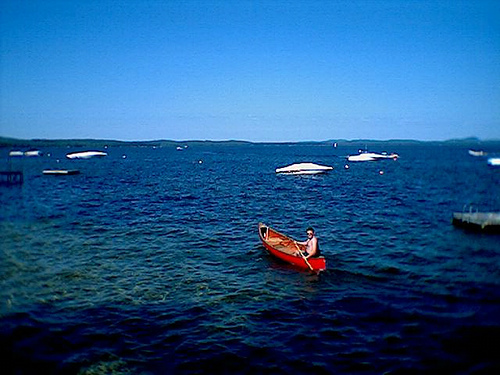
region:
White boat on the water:
[276, 158, 336, 177]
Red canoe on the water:
[255, 222, 328, 274]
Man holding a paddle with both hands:
[293, 240, 319, 282]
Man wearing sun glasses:
[306, 231, 314, 235]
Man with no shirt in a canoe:
[293, 227, 321, 259]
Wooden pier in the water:
[450, 205, 499, 230]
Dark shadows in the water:
[2, 298, 499, 369]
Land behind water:
[0, 133, 498, 145]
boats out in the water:
[2, 145, 499, 373]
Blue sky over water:
[1, 1, 498, 136]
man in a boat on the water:
[255, 216, 330, 279]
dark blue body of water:
[0, 146, 497, 373]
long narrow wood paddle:
[291, 239, 321, 276]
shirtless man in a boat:
[293, 227, 319, 254]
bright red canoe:
[257, 220, 325, 277]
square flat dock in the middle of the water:
[38, 166, 81, 177]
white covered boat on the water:
[271, 158, 336, 179]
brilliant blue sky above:
[0, 0, 499, 142]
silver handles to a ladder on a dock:
[462, 200, 480, 217]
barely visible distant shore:
[0, 134, 499, 147]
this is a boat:
[255, 194, 354, 285]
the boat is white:
[192, 149, 334, 191]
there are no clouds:
[210, 44, 299, 197]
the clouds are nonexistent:
[193, 1, 336, 100]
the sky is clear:
[200, 29, 300, 106]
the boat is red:
[240, 233, 379, 318]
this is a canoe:
[275, 172, 379, 362]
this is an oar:
[288, 218, 318, 306]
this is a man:
[285, 239, 314, 264]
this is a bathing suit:
[279, 246, 319, 259]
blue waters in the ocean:
[164, 279, 199, 292]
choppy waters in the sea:
[247, 297, 338, 336]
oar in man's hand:
[287, 233, 314, 273]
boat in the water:
[252, 236, 365, 268]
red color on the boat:
[276, 255, 322, 272]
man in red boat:
[296, 225, 327, 267]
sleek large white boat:
[267, 152, 352, 191]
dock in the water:
[444, 194, 491, 246]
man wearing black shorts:
[294, 248, 314, 258]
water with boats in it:
[4, 141, 488, 363]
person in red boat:
[259, 203, 342, 275]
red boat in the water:
[239, 228, 328, 278]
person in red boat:
[293, 215, 320, 275]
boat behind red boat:
[269, 157, 332, 182]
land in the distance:
[6, 125, 170, 150]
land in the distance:
[304, 130, 482, 138]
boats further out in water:
[4, 146, 216, 167]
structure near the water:
[455, 200, 499, 239]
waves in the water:
[281, 192, 390, 212]